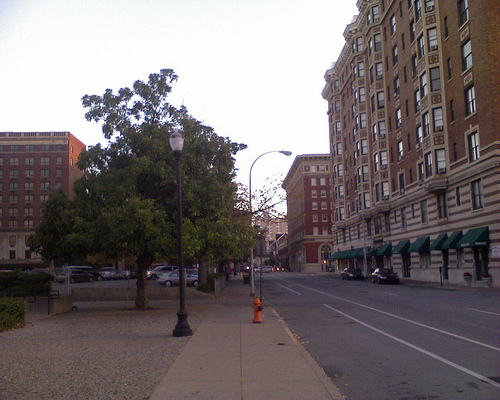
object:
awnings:
[320, 215, 487, 261]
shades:
[329, 224, 487, 267]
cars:
[375, 270, 397, 287]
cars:
[335, 260, 360, 282]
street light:
[169, 132, 194, 337]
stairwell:
[30, 289, 55, 316]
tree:
[26, 70, 252, 310]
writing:
[0, 130, 72, 139]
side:
[1, 131, 84, 157]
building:
[0, 132, 89, 283]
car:
[371, 268, 396, 281]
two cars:
[338, 260, 403, 291]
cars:
[38, 259, 205, 286]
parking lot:
[57, 269, 201, 302]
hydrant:
[249, 295, 268, 327]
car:
[272, 262, 288, 276]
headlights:
[275, 267, 284, 269]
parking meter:
[437, 265, 443, 285]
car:
[158, 270, 199, 287]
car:
[145, 263, 177, 276]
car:
[95, 267, 125, 279]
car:
[68, 265, 105, 280]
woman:
[458, 270, 475, 285]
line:
[297, 291, 454, 398]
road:
[270, 259, 496, 398]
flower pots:
[459, 269, 491, 287]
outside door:
[470, 245, 488, 281]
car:
[339, 266, 364, 281]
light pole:
[164, 122, 205, 334]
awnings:
[416, 225, 486, 259]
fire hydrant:
[250, 297, 265, 324]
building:
[321, 0, 498, 291]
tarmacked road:
[322, 283, 389, 355]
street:
[258, 235, 470, 395]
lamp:
[168, 127, 193, 334]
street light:
[247, 149, 293, 299]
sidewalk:
[152, 271, 340, 398]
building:
[320, 205, 498, 269]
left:
[318, 205, 496, 325]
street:
[77, 261, 195, 400]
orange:
[213, 296, 286, 347]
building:
[38, 134, 72, 288]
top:
[242, 113, 313, 246]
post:
[151, 116, 190, 347]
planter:
[453, 269, 485, 289]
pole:
[240, 166, 258, 304]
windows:
[388, 255, 489, 275]